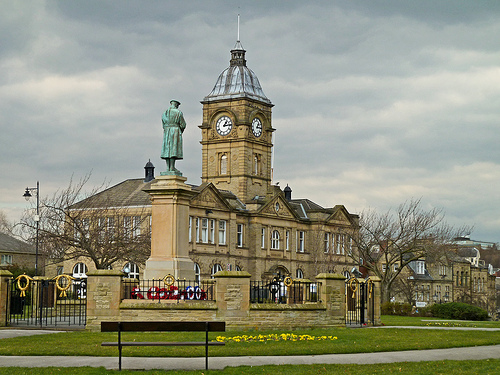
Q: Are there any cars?
A: No, there are no cars.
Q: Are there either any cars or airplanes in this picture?
A: No, there are no cars or airplanes.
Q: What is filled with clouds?
A: The sky is filled with clouds.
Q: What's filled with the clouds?
A: The sky is filled with clouds.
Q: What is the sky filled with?
A: The sky is filled with clouds.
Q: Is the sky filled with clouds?
A: Yes, the sky is filled with clouds.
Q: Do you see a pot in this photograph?
A: No, there are no pots.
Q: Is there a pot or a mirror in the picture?
A: No, there are no pots or mirrors.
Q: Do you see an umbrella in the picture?
A: No, there are no umbrellas.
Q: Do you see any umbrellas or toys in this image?
A: No, there are no umbrellas or toys.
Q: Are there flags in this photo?
A: No, there are no flags.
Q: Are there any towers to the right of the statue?
A: Yes, there is a tower to the right of the statue.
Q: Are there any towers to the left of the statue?
A: No, the tower is to the right of the statue.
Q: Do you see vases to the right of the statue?
A: No, there is a tower to the right of the statue.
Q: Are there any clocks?
A: Yes, there is a clock.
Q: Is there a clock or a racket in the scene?
A: Yes, there is a clock.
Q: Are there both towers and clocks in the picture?
A: Yes, there are both a clock and a tower.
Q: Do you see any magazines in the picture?
A: No, there are no magazines.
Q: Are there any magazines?
A: No, there are no magazines.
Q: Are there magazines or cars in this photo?
A: No, there are no magazines or cars.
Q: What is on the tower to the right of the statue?
A: The clock is on the tower.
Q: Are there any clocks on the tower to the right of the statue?
A: Yes, there is a clock on the tower.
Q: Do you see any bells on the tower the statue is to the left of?
A: No, there is a clock on the tower.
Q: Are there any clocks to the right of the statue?
A: Yes, there is a clock to the right of the statue.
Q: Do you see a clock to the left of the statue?
A: No, the clock is to the right of the statue.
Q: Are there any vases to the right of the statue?
A: No, there is a clock to the right of the statue.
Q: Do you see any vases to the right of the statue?
A: No, there is a clock to the right of the statue.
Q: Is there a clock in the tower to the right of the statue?
A: Yes, there is a clock in the tower.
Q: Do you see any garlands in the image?
A: No, there are no garlands.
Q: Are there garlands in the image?
A: No, there are no garlands.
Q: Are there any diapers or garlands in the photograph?
A: No, there are no garlands or diapers.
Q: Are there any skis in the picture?
A: No, there are no skis.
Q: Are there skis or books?
A: No, there are no skis or books.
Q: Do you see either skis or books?
A: No, there are no skis or books.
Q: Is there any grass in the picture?
A: Yes, there is grass.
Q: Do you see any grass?
A: Yes, there is grass.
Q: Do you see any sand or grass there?
A: Yes, there is grass.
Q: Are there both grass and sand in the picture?
A: No, there is grass but no sand.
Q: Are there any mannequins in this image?
A: No, there are no mannequins.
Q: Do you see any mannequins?
A: No, there are no mannequins.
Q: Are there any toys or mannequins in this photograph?
A: No, there are no mannequins or toys.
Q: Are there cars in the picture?
A: No, there are no cars.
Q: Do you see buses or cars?
A: No, there are no cars or buses.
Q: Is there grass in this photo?
A: Yes, there is grass.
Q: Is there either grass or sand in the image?
A: Yes, there is grass.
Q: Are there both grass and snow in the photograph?
A: No, there is grass but no snow.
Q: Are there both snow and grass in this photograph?
A: No, there is grass but no snow.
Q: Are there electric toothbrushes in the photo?
A: No, there are no electric toothbrushes.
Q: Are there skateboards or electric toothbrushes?
A: No, there are no electric toothbrushes or skateboards.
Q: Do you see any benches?
A: Yes, there is a bench.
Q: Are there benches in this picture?
A: Yes, there is a bench.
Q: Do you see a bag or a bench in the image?
A: Yes, there is a bench.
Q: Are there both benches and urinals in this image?
A: No, there is a bench but no urinals.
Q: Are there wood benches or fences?
A: Yes, there is a wood bench.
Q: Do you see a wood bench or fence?
A: Yes, there is a wood bench.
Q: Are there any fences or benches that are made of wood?
A: Yes, the bench is made of wood.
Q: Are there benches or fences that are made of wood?
A: Yes, the bench is made of wood.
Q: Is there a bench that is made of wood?
A: Yes, there is a bench that is made of wood.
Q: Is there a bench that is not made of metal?
A: Yes, there is a bench that is made of wood.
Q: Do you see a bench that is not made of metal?
A: Yes, there is a bench that is made of wood.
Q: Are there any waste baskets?
A: No, there are no waste baskets.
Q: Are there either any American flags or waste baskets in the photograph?
A: No, there are no waste baskets or American flags.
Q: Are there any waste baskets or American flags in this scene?
A: No, there are no waste baskets or American flags.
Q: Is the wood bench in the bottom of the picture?
A: Yes, the bench is in the bottom of the image.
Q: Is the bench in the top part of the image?
A: No, the bench is in the bottom of the image.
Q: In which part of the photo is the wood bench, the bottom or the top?
A: The bench is in the bottom of the image.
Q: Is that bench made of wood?
A: Yes, the bench is made of wood.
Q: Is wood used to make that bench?
A: Yes, the bench is made of wood.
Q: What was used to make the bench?
A: The bench is made of wood.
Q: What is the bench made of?
A: The bench is made of wood.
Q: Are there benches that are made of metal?
A: No, there is a bench but it is made of wood.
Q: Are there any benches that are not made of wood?
A: No, there is a bench but it is made of wood.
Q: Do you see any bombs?
A: No, there are no bombs.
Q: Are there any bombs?
A: No, there are no bombs.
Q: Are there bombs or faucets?
A: No, there are no bombs or faucets.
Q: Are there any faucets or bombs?
A: No, there are no bombs or faucets.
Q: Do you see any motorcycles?
A: No, there are no motorcycles.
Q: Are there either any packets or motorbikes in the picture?
A: No, there are no motorbikes or packets.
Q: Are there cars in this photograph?
A: No, there are no cars.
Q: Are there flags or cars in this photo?
A: No, there are no cars or flags.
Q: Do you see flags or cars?
A: No, there are no cars or flags.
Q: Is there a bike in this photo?
A: No, there are no bikes.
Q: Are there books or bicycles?
A: No, there are no bicycles or books.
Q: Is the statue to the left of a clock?
A: Yes, the statue is to the left of a clock.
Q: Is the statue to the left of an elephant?
A: No, the statue is to the left of a clock.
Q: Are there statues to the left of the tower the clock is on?
A: Yes, there is a statue to the left of the tower.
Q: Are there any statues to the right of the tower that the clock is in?
A: No, the statue is to the left of the tower.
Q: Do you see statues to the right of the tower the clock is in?
A: No, the statue is to the left of the tower.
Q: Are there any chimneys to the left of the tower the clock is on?
A: No, there is a statue to the left of the tower.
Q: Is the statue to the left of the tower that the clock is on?
A: Yes, the statue is to the left of the tower.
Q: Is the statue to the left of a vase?
A: No, the statue is to the left of the tower.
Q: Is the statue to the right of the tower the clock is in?
A: No, the statue is to the left of the tower.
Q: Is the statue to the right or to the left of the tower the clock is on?
A: The statue is to the left of the tower.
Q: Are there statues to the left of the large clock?
A: Yes, there is a statue to the left of the clock.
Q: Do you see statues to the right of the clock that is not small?
A: No, the statue is to the left of the clock.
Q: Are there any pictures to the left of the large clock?
A: No, there is a statue to the left of the clock.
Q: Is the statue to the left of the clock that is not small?
A: Yes, the statue is to the left of the clock.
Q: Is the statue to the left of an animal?
A: No, the statue is to the left of the clock.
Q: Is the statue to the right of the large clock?
A: No, the statue is to the left of the clock.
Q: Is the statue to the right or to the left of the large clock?
A: The statue is to the left of the clock.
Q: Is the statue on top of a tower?
A: Yes, the statue is on top of a tower.